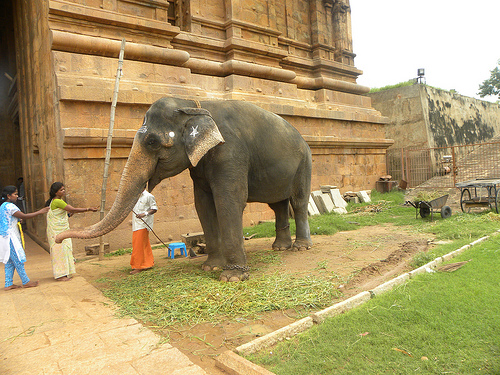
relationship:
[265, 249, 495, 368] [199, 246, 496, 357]
grass on ground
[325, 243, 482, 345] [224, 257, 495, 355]
grass on ground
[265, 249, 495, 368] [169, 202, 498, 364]
grass on ground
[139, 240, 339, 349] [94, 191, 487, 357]
grass on ground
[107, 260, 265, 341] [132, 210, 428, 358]
grass on ground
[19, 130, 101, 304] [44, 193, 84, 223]
woman has a shirt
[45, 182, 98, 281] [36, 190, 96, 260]
woman wearing a sarong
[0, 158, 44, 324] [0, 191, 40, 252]
woman wearing a shirt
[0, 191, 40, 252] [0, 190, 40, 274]
shirt has a design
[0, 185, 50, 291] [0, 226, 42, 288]
woman wearing pants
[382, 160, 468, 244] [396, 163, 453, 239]
wheelbarrow full of grass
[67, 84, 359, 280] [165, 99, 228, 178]
elephant has an ear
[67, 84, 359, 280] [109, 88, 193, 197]
elephant has a face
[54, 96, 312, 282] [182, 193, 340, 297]
elephant has a leg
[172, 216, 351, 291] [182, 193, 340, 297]
chain around leg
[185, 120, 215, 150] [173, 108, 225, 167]
star painted on ear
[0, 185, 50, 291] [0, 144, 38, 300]
woman dressed in indian outfit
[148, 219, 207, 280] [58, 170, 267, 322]
stool sitting on ground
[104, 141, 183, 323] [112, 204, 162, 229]
man has a hand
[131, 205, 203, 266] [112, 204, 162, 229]
stick in hand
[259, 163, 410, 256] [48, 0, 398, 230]
pavers stacked against wall